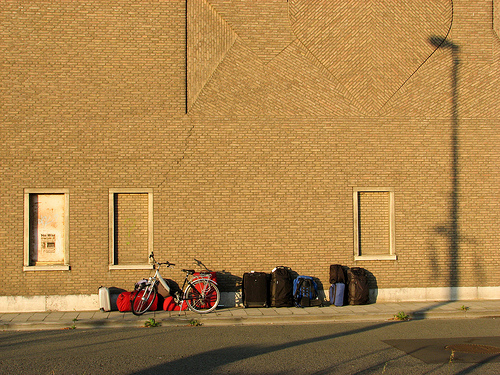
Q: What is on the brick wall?
A: The street light shadow.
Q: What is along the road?
A: The cement sidewalk.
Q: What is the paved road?
A: Empty.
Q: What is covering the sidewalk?
A: The grey concrete.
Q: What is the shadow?
A: The street lamp pole.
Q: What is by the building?
A: The suitcases.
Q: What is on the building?
A: The windows.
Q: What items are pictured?
A: Luggage.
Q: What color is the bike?
A: White.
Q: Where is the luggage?
A: Against wall.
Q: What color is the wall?
A: Brown.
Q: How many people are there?
A: Zero.